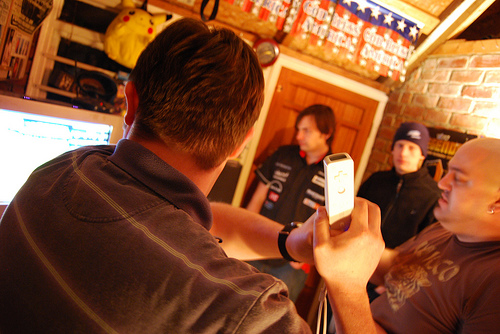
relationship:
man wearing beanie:
[355, 122, 443, 250] [392, 121, 429, 157]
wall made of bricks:
[422, 77, 479, 124] [386, 36, 480, 137]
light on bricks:
[476, 111, 498, 137] [382, 57, 498, 133]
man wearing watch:
[2, 17, 383, 332] [273, 220, 300, 263]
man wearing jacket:
[359, 110, 442, 245] [358, 160, 448, 243]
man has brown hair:
[2, 17, 383, 332] [113, 10, 279, 175]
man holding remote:
[0, 17, 385, 334] [323, 152, 353, 232]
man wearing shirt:
[0, 17, 385, 334] [3, 141, 310, 328]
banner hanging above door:
[214, 0, 427, 84] [241, 68, 378, 225]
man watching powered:
[0, 17, 385, 334] [0, 108, 113, 206]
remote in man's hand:
[323, 152, 353, 232] [307, 193, 402, 300]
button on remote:
[329, 177, 352, 198] [304, 152, 355, 332]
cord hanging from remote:
[313, 274, 340, 331] [296, 137, 369, 324]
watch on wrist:
[278, 214, 299, 271] [273, 213, 300, 269]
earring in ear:
[487, 210, 499, 220] [481, 191, 498, 214]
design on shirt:
[397, 249, 424, 300] [382, 225, 499, 325]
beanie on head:
[392, 121, 429, 157] [386, 133, 434, 174]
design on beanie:
[408, 125, 418, 141] [360, 108, 450, 203]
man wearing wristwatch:
[2, 17, 383, 332] [277, 219, 292, 261]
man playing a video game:
[2, 17, 383, 332] [312, 151, 384, 281]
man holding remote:
[0, 17, 385, 334] [304, 151, 366, 211]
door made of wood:
[237, 63, 379, 208] [275, 71, 317, 120]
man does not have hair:
[305, 152, 498, 332] [422, 143, 497, 251]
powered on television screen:
[15, 114, 74, 181] [2, 107, 113, 220]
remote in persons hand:
[323, 152, 353, 232] [310, 195, 375, 275]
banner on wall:
[214, 0, 422, 85] [156, 0, 439, 86]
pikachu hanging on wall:
[103, 0, 172, 67] [54, 50, 88, 68]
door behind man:
[237, 66, 379, 207] [243, 102, 336, 308]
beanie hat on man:
[375, 104, 437, 158] [374, 140, 425, 197]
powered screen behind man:
[0, 108, 113, 206] [28, 170, 180, 233]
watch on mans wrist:
[278, 222, 299, 262] [233, 201, 328, 264]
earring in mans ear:
[487, 210, 494, 214] [469, 187, 499, 204]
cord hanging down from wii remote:
[313, 296, 333, 334] [318, 144, 360, 227]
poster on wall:
[420, 129, 463, 186] [338, 42, 498, 239]